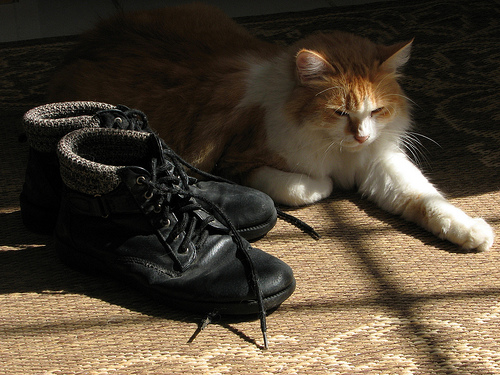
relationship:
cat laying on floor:
[52, 4, 495, 252] [281, 209, 481, 370]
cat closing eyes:
[50, 7, 499, 257] [324, 93, 406, 141]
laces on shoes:
[153, 151, 327, 355] [12, 90, 302, 334]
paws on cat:
[308, 179, 495, 261] [95, 9, 477, 276]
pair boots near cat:
[48, 91, 255, 273] [106, 19, 484, 286]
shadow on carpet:
[0, 5, 499, 330] [0, 0, 496, 371]